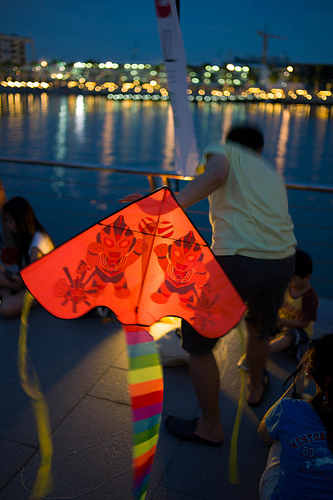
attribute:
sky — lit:
[4, 4, 331, 63]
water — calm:
[11, 98, 332, 255]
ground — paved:
[14, 302, 326, 499]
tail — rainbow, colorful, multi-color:
[123, 321, 163, 495]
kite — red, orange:
[24, 196, 247, 330]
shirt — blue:
[265, 401, 330, 499]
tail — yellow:
[19, 290, 56, 498]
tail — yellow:
[226, 324, 246, 490]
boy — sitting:
[277, 253, 319, 354]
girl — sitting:
[2, 196, 55, 318]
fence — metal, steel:
[2, 165, 331, 318]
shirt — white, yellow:
[202, 143, 299, 254]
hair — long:
[13, 201, 41, 260]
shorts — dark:
[193, 249, 299, 331]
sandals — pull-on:
[155, 369, 273, 448]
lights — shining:
[14, 68, 331, 104]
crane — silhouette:
[255, 27, 295, 63]